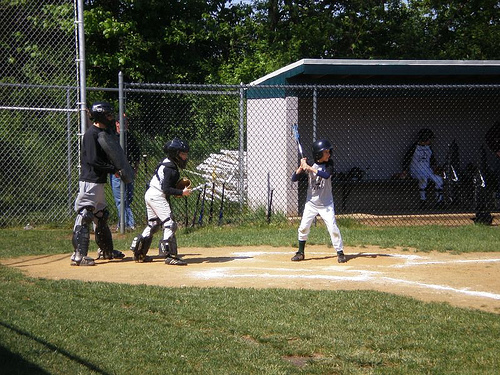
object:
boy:
[292, 141, 348, 262]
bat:
[293, 122, 303, 165]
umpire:
[71, 101, 127, 263]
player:
[399, 126, 444, 207]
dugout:
[246, 62, 496, 229]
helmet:
[311, 138, 329, 161]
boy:
[132, 143, 187, 266]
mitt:
[172, 177, 192, 197]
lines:
[190, 272, 381, 282]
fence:
[120, 1, 499, 215]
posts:
[234, 83, 246, 215]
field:
[7, 264, 498, 368]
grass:
[5, 290, 498, 366]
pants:
[295, 204, 342, 247]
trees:
[231, 2, 276, 78]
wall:
[247, 101, 300, 219]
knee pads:
[163, 216, 176, 231]